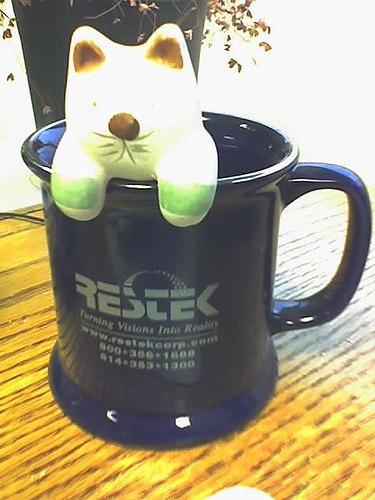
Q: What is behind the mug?
A: A flower pot.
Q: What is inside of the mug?
A: A cat.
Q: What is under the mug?
A: A table.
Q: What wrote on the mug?
A: A company.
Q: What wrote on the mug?
A: A company.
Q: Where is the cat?
A: Cup.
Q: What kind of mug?
A: Coffee.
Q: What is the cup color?
A: Black.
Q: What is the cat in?
A: Cup.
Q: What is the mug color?
A: Black.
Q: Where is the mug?
A: Table.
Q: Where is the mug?
A: Table.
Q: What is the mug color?
A: Black.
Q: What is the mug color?
A: Black.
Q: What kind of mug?
A: Coffee.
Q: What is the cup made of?
A: Ceramic.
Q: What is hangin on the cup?
A: A cat ornament.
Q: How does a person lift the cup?
A: By the handle.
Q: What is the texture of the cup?
A: Glossy.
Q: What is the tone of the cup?
A: Dark.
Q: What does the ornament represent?
A: A cat?.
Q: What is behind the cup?
A: A vase.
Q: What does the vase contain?
A: Leaves.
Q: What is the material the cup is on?
A: Wood.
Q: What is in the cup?
A: A cat.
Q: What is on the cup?
A: Writing on a cup.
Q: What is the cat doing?
A: Hanging over a cup.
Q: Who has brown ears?
A: The cat.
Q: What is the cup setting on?
A: A wood table.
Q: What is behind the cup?
A: A vase with flowers in it.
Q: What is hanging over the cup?
A: The cat paws.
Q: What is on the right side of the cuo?
A: A handle.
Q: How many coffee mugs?
A: One.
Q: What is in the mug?
A: A cat.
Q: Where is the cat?
A: In the mug.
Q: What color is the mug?
A: Blue.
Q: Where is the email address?
A: On the mug.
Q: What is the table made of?
A: Wood.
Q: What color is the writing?
A: Grey.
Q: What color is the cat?
A: White.